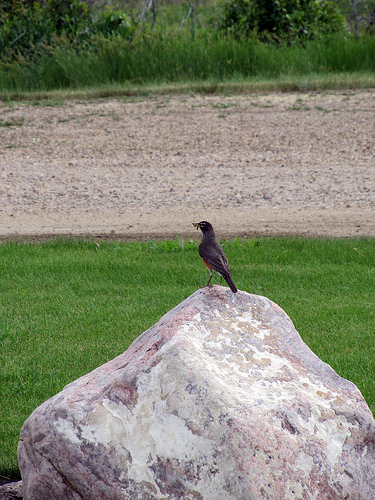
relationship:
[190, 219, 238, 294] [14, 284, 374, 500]
bird on top of rock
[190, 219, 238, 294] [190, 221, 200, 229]
bird has beak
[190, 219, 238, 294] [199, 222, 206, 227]
bird has eye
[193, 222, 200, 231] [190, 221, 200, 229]
worm held in beak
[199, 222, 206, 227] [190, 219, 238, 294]
eye on front of bird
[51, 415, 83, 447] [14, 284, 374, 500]
speck on top of rock